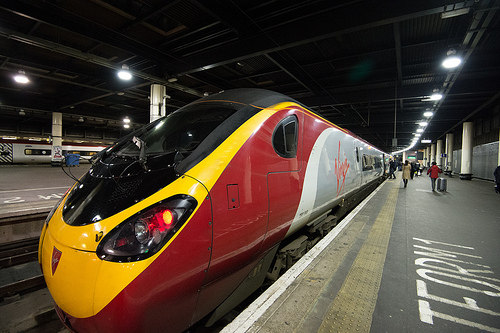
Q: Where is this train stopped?
A: Station.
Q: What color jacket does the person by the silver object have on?
A: Red.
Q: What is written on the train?
A: Virgin.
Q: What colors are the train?
A: Red,white,gray and yellow.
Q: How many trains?
A: One.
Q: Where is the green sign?
A: At the end of the platform.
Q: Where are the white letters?
A: On platform.